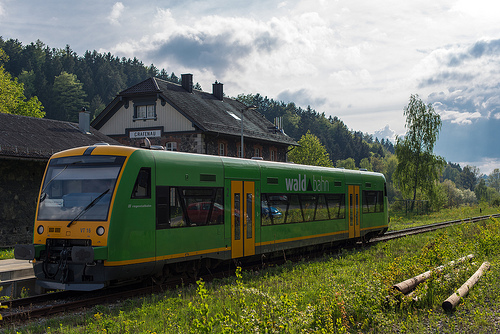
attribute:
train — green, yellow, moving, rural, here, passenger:
[143, 173, 359, 258]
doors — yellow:
[231, 188, 248, 255]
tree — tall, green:
[392, 96, 447, 202]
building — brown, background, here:
[116, 82, 286, 148]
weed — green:
[20, 105, 39, 113]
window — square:
[156, 193, 214, 227]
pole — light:
[454, 289, 481, 308]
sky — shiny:
[476, 123, 488, 132]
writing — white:
[277, 172, 328, 192]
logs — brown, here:
[405, 265, 476, 299]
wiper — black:
[70, 189, 108, 228]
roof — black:
[213, 98, 250, 129]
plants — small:
[404, 251, 452, 269]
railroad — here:
[1, 259, 94, 315]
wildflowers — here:
[25, 110, 42, 116]